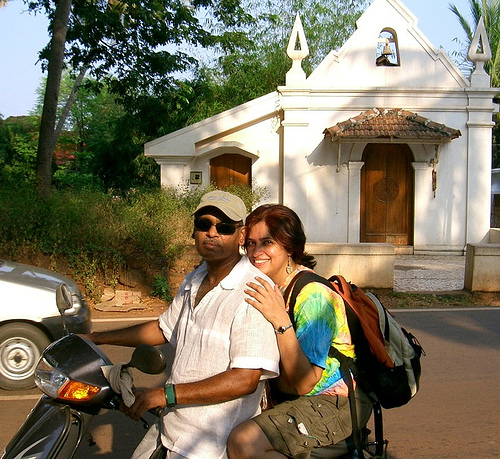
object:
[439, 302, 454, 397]
ground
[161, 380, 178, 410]
wristband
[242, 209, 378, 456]
woman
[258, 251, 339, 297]
shoulder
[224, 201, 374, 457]
woman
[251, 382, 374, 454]
shorts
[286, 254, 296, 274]
earring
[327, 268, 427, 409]
backpack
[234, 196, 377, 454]
woman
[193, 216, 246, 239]
sunglasses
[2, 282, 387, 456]
moped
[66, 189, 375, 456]
people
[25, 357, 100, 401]
front lights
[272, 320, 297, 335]
watch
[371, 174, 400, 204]
decoration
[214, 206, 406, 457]
woman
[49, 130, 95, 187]
roof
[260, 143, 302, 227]
floor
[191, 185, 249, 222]
hat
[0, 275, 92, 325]
car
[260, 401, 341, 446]
shorts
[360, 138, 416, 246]
door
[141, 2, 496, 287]
church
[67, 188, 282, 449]
man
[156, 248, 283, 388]
shirt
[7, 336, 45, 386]
silvery cap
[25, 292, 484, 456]
street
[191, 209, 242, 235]
eyes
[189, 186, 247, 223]
cap.